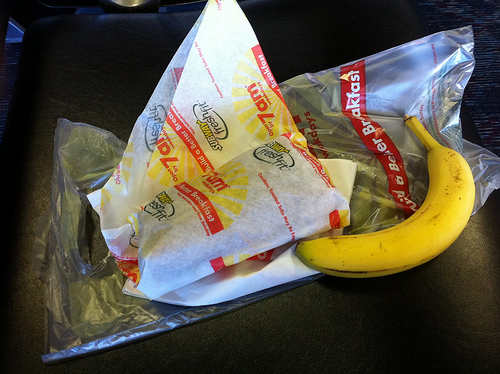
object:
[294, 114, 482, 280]
banana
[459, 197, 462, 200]
spot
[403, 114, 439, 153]
top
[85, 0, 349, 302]
wrapper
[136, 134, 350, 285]
sandwich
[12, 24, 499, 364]
bag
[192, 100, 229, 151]
logo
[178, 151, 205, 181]
yellow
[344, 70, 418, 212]
logo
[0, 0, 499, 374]
table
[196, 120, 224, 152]
subway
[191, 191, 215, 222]
breakfast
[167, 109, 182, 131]
words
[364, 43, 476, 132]
reflection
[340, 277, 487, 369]
shadow